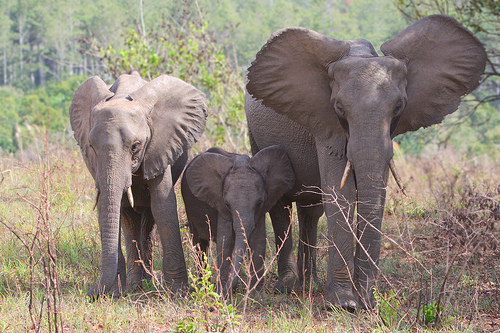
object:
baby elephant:
[178, 143, 298, 305]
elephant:
[241, 11, 492, 314]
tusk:
[387, 157, 410, 198]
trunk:
[85, 183, 125, 304]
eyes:
[333, 99, 349, 117]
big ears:
[378, 13, 489, 139]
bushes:
[94, 20, 250, 149]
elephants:
[66, 68, 213, 307]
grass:
[57, 228, 88, 281]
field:
[0, 143, 500, 333]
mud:
[393, 170, 409, 197]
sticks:
[0, 215, 43, 333]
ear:
[248, 144, 296, 217]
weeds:
[467, 203, 480, 244]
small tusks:
[127, 186, 135, 209]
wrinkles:
[330, 265, 359, 287]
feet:
[318, 275, 364, 315]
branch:
[485, 54, 497, 74]